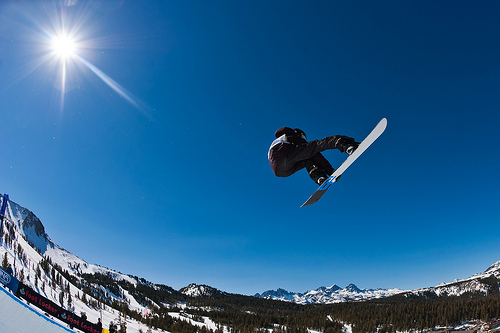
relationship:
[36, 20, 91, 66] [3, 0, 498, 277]
sun in sky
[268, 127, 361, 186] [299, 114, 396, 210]
man on snowboard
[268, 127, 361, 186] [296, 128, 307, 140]
man wearing goggle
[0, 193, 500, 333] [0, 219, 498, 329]
hill above forest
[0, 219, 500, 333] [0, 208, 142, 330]
forest lining ski slope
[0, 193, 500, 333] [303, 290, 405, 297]
hill with snow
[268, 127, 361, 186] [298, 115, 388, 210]
man with snowboard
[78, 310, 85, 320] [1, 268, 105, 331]
people near banner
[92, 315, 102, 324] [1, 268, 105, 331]
people near banner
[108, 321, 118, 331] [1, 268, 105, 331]
people near banner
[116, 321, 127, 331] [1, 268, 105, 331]
people near banner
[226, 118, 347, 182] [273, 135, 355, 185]
man wearing pants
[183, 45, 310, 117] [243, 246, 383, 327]
sky above hills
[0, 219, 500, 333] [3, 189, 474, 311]
forest along hills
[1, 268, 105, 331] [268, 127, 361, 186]
banner on man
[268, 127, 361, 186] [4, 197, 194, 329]
man on hill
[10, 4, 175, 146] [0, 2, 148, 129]
ray of sun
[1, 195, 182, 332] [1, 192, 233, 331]
hill covered with snow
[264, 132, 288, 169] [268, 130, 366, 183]
back of skater